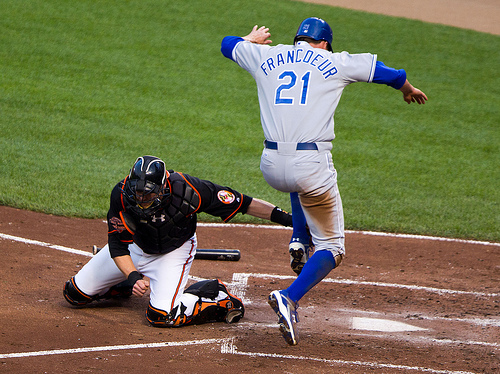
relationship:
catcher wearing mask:
[65, 138, 295, 324] [122, 182, 168, 219]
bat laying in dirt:
[183, 246, 244, 262] [2, 207, 499, 368]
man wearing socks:
[209, 13, 458, 342] [281, 249, 336, 317]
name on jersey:
[255, 48, 340, 82] [228, 32, 378, 150]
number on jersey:
[275, 64, 315, 114] [228, 32, 378, 150]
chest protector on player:
[128, 170, 196, 253] [65, 138, 295, 324]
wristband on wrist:
[123, 271, 146, 293] [122, 270, 146, 280]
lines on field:
[183, 262, 282, 367] [2, 0, 489, 373]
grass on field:
[4, 1, 500, 234] [2, 0, 489, 373]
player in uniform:
[209, 13, 458, 342] [208, 38, 413, 334]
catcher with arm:
[65, 138, 295, 324] [177, 172, 298, 243]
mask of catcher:
[122, 182, 168, 219] [65, 138, 295, 324]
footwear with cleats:
[265, 237, 325, 358] [271, 306, 295, 342]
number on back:
[275, 64, 315, 114] [262, 43, 330, 144]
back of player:
[262, 43, 330, 144] [209, 13, 458, 342]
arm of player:
[335, 51, 434, 112] [209, 13, 458, 342]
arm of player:
[215, 17, 280, 75] [209, 13, 458, 342]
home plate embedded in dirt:
[351, 305, 433, 343] [2, 207, 499, 368]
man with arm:
[219, 16, 428, 347] [335, 51, 434, 112]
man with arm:
[219, 16, 428, 347] [215, 17, 280, 75]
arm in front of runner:
[177, 172, 298, 243] [209, 13, 458, 342]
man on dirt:
[219, 16, 428, 347] [2, 207, 499, 368]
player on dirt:
[65, 138, 295, 324] [2, 207, 499, 368]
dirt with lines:
[2, 207, 499, 368] [183, 262, 282, 367]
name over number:
[255, 48, 340, 82] [275, 64, 315, 114]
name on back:
[255, 48, 340, 82] [262, 43, 330, 144]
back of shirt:
[262, 43, 330, 144] [228, 32, 378, 150]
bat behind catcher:
[183, 246, 244, 262] [65, 138, 295, 324]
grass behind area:
[4, 1, 500, 234] [2, 207, 499, 368]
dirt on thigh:
[301, 191, 337, 245] [296, 176, 350, 251]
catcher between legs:
[65, 138, 295, 324] [258, 150, 353, 349]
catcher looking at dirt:
[65, 138, 295, 324] [2, 207, 499, 368]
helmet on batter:
[292, 14, 337, 45] [209, 13, 458, 342]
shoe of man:
[282, 234, 317, 272] [219, 16, 428, 347]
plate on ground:
[351, 305, 433, 343] [2, 207, 499, 368]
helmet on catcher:
[123, 153, 174, 195] [65, 138, 295, 324]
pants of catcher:
[76, 231, 197, 316] [65, 138, 295, 324]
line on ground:
[3, 337, 228, 355] [2, 207, 499, 368]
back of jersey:
[262, 43, 330, 144] [228, 32, 378, 150]